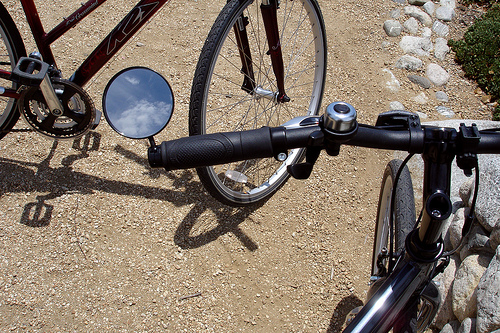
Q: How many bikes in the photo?
A: Two.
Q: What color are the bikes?
A: Black.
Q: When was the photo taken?
A: Day time.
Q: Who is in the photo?
A: Just bikes.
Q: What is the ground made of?
A: Dirt.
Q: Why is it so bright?
A: Sunny.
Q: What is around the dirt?
A: Rocks.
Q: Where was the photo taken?
A: On a dirt road.